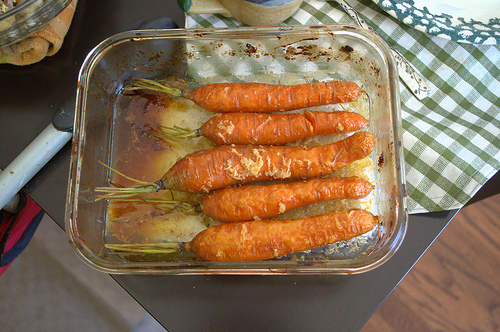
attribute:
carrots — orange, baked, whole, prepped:
[114, 79, 379, 261]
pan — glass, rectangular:
[69, 24, 405, 278]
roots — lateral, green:
[98, 79, 204, 264]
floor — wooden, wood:
[1, 7, 499, 329]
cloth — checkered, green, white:
[185, 1, 499, 213]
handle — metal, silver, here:
[2, 99, 71, 218]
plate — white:
[373, 0, 498, 47]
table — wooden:
[2, 2, 476, 332]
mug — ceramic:
[184, 1, 316, 34]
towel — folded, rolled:
[4, 2, 77, 66]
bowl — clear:
[2, 3, 77, 51]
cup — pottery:
[180, 2, 309, 27]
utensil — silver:
[331, 0, 435, 103]